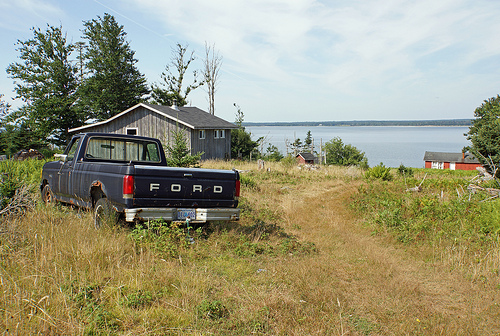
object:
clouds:
[140, 0, 500, 123]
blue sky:
[1, 0, 499, 122]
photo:
[0, 0, 498, 334]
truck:
[41, 130, 242, 234]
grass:
[0, 207, 340, 336]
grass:
[343, 177, 498, 249]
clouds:
[0, 0, 103, 121]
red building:
[422, 150, 490, 172]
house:
[60, 102, 237, 166]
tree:
[461, 94, 498, 186]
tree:
[0, 22, 81, 157]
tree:
[71, 13, 151, 121]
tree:
[147, 42, 209, 106]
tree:
[320, 136, 371, 168]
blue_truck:
[40, 132, 239, 231]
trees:
[196, 41, 218, 117]